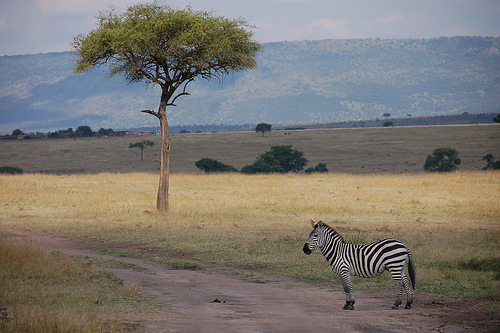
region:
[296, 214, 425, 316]
a zebra standing on a road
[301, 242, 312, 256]
the zebra has a black snout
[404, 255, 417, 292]
the tail on the zebra is black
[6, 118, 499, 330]
the zebra is in the plains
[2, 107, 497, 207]
trees are scattered around the plains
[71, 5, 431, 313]
the animal is near a tree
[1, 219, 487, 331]
the plains have a dirt road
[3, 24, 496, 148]
hills are in the background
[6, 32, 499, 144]
the hills are covered with vegetation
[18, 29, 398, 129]
a long mountain in distance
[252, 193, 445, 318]
a zebra is standing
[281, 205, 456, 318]
the zebra is looking to the right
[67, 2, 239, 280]
a tree in the field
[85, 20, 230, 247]
the tree is skinny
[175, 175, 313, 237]
the grass is yellow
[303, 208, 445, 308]
the zebra has stripes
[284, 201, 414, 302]
a black and white zebra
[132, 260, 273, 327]
the ground is brown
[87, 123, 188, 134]
houses in the distance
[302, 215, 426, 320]
A black and white zebra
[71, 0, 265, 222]
A lone green tree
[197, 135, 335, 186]
Three bushes clustered together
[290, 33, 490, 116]
a mountain range in the background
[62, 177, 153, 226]
Yellow, dry grass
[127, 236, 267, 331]
A sandy walkway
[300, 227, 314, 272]
The black nose of a zebra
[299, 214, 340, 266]
The head of a zebra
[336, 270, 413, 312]
The zebras front and back legs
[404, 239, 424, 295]
The zebras black hairy tail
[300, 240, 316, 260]
The nose and mouth area of the zebra.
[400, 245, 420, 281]
The tail of the zebra.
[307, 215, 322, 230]
The ears of the zebra.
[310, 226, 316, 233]
The eye of the zebra.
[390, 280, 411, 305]
The back legs of the zebra.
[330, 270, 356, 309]
The front legs of the zebra.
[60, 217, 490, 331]
The dirt path where the zebra is standing.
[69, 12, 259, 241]
The tall tree in the pasture.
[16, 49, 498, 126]
The hills in the distance.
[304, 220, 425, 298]
The stripes of the zebra.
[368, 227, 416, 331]
the zebra has tail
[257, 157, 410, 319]
the zebra has tail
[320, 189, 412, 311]
the zebra has tail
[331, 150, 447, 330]
the zebra has tail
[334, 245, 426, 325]
the zebra has tail